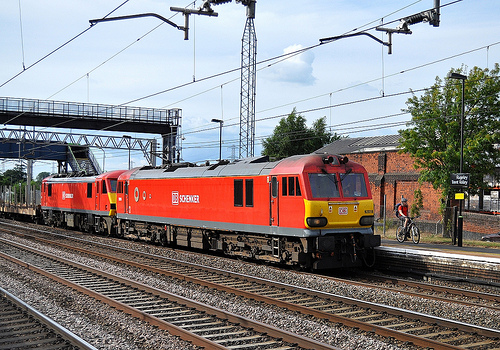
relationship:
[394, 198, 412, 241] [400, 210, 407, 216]
bicycler in a shirt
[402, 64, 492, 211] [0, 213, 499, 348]
tree adjacent to rails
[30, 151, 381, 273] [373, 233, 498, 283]
train at platform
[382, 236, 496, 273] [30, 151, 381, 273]
platform near train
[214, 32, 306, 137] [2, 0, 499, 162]
pillar supporting cables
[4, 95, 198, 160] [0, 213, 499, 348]
bridge across rails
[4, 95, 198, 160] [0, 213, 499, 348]
bridge overhead rails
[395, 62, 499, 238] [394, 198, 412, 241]
tree near bicycler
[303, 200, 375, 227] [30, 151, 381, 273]
front of train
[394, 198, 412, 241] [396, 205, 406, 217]
bicycler wearing shirt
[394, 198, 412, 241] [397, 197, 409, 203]
bicycler wearing helmet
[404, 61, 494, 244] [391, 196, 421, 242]
tree near bicycler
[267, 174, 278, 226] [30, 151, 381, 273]
door on train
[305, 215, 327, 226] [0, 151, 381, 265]
headlight on train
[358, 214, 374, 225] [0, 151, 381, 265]
headlight on train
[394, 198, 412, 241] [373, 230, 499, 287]
bicycler biking on platform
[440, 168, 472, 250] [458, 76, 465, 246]
sign on pole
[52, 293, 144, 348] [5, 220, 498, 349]
gravel covering rails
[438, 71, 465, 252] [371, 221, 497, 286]
pole on platform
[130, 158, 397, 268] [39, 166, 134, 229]
train matching train